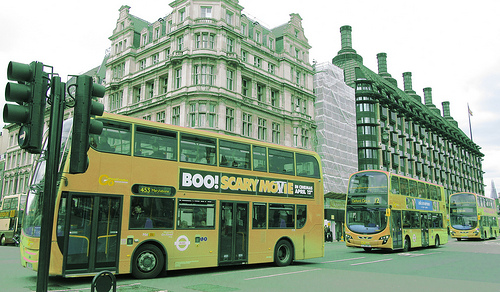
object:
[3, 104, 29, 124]
traffic signals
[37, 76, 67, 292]
black pole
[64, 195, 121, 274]
doors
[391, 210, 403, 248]
doors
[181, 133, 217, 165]
window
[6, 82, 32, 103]
traffic signals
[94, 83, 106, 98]
traffic signals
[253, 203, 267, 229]
window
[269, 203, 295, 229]
window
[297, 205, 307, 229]
window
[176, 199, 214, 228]
window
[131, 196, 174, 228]
window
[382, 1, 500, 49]
sky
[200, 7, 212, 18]
dormer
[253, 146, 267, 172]
windows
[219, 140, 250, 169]
window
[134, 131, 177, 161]
window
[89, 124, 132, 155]
window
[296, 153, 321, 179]
window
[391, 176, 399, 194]
window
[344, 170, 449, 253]
bus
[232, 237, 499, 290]
green street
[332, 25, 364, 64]
roof stack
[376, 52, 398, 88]
roof stack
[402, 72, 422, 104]
roof stack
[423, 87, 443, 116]
roof stack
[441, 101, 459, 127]
roof stack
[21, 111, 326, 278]
bus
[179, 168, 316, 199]
billboard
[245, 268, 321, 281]
lines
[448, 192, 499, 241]
bus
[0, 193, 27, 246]
bus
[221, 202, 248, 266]
doors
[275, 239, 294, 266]
back wheel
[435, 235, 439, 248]
back wheel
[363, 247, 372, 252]
tire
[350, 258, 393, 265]
line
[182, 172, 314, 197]
advertisement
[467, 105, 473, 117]
flag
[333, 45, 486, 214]
building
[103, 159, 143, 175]
yellow part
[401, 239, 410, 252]
tires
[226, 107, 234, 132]
window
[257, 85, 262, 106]
window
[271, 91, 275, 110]
window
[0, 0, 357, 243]
building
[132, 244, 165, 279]
front tire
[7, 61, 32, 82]
signal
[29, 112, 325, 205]
level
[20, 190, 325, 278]
level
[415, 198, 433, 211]
advertisement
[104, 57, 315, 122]
level